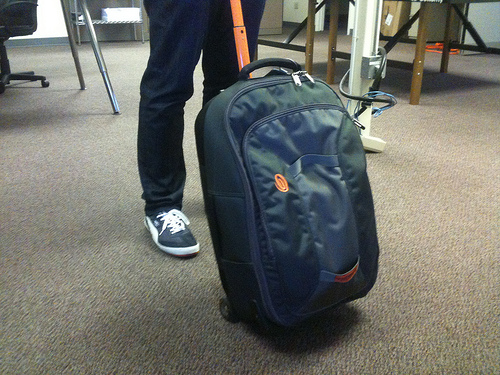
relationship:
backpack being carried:
[202, 54, 385, 327] [219, 4, 256, 52]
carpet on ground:
[7, 133, 145, 351] [20, 92, 498, 358]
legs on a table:
[394, 3, 434, 115] [313, 0, 495, 4]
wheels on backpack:
[217, 300, 234, 320] [202, 54, 385, 327]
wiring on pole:
[336, 64, 396, 120] [353, 0, 382, 145]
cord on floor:
[428, 39, 444, 60] [383, 34, 498, 364]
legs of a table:
[394, 3, 434, 115] [313, 0, 495, 4]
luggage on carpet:
[202, 54, 385, 327] [7, 133, 145, 351]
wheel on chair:
[41, 82, 51, 90] [0, 0, 51, 91]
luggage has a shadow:
[202, 54, 385, 327] [95, 295, 254, 372]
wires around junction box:
[339, 76, 401, 111] [365, 55, 388, 80]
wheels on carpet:
[217, 300, 234, 320] [7, 133, 145, 351]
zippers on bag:
[290, 73, 315, 92] [202, 54, 385, 327]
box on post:
[365, 55, 388, 80] [353, 0, 382, 145]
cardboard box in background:
[381, 0, 407, 38] [337, 5, 456, 57]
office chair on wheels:
[0, 0, 51, 91] [42, 77, 53, 87]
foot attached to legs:
[141, 207, 200, 257] [146, 1, 255, 225]